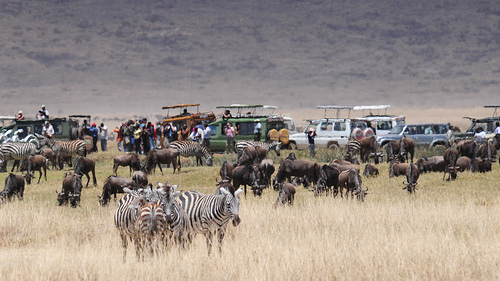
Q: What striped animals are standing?
A: Zebras.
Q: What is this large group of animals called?
A: Herd.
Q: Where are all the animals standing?
A: Field.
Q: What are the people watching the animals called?
A: Spectators.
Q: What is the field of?
A: Grass.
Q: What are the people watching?
A: Animals.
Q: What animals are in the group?
A: Zebras.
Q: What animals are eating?
A: Cattle.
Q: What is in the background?
A: Plains.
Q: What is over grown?
A: Grass.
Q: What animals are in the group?
A: Zebras.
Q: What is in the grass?
A: Animals.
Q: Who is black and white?
A: Zebras.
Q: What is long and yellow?
A: Grass.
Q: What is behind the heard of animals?
A: Row of cars.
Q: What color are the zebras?
A: Black and white.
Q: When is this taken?
A: During the daytime.